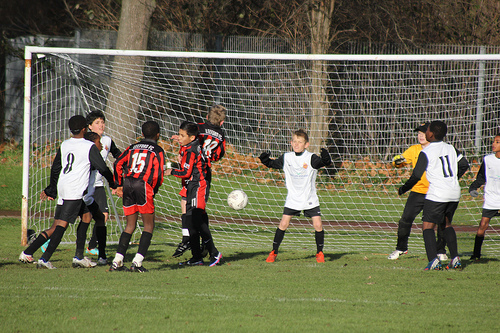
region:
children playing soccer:
[24, 77, 499, 301]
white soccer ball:
[220, 180, 257, 220]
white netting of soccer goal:
[14, 16, 494, 248]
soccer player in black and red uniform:
[101, 94, 181, 279]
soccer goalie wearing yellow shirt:
[367, 119, 429, 260]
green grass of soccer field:
[290, 268, 413, 318]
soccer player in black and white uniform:
[393, 114, 474, 264]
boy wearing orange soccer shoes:
[246, 121, 343, 286]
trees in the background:
[92, 0, 356, 145]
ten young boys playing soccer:
[11, 76, 498, 276]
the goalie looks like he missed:
[268, 113, 358, 272]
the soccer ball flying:
[227, 186, 259, 224]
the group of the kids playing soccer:
[46, 96, 496, 275]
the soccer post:
[30, 31, 467, 60]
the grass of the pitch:
[208, 276, 333, 330]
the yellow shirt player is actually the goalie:
[410, 120, 434, 227]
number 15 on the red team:
[125, 113, 202, 262]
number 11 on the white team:
[426, 133, 477, 240]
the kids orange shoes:
[248, 254, 365, 284]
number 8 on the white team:
[59, 118, 115, 271]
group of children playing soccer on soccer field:
[19, 98, 499, 273]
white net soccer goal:
[17, 44, 499, 269]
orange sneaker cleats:
[263, 251, 327, 265]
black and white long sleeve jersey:
[403, 139, 469, 205]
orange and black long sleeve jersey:
[112, 141, 166, 188]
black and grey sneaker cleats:
[17, 246, 55, 271]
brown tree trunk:
[101, 1, 157, 137]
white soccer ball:
[223, 187, 251, 211]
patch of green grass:
[158, 285, 270, 322]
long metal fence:
[1, 33, 498, 154]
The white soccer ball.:
[222, 185, 250, 208]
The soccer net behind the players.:
[25, 48, 499, 263]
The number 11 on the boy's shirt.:
[436, 153, 455, 184]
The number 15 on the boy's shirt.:
[128, 145, 151, 181]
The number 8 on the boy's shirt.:
[64, 145, 78, 183]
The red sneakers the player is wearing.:
[264, 244, 339, 270]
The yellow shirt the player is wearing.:
[397, 137, 439, 187]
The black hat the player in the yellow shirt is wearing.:
[412, 122, 432, 137]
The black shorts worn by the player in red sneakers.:
[279, 206, 330, 216]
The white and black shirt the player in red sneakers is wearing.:
[258, 147, 344, 194]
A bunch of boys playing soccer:
[18, 55, 498, 261]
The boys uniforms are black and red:
[116, 102, 242, 283]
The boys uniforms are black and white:
[260, 128, 499, 262]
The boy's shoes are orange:
[257, 126, 342, 293]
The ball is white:
[226, 184, 257, 212]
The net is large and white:
[11, 50, 498, 269]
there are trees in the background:
[72, 0, 499, 180]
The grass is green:
[2, 143, 498, 331]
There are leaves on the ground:
[38, 139, 485, 190]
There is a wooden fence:
[8, 28, 499, 165]